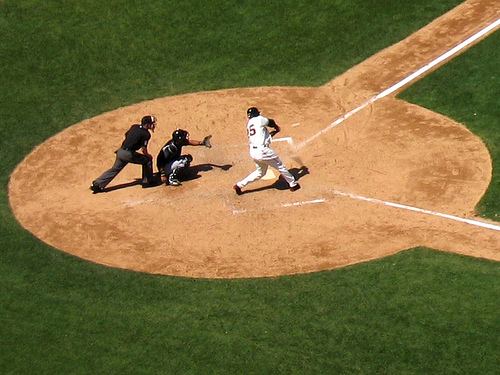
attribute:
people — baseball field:
[82, 96, 308, 221]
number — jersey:
[240, 125, 270, 141]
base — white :
[259, 167, 279, 187]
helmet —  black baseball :
[235, 102, 271, 124]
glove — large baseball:
[201, 133, 216, 149]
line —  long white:
[355, 67, 451, 228]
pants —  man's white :
[231, 160, 301, 192]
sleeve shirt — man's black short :
[118, 120, 155, 153]